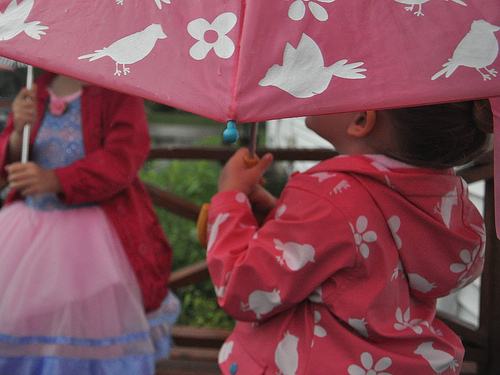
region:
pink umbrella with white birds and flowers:
[5, 5, 491, 127]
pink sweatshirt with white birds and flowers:
[200, 101, 485, 368]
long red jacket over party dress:
[0, 66, 170, 311]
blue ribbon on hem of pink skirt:
[2, 290, 192, 370]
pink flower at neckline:
[36, 76, 81, 112]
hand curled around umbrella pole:
[10, 65, 40, 157]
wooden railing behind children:
[115, 130, 491, 360]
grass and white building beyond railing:
[140, 110, 495, 350]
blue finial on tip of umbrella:
[211, 111, 241, 142]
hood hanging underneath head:
[343, 105, 491, 286]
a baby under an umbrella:
[208, 43, 481, 374]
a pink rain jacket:
[213, 158, 490, 372]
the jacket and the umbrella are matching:
[7, 0, 484, 372]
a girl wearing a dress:
[8, 79, 198, 374]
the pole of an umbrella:
[14, 57, 49, 206]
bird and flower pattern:
[37, 8, 304, 80]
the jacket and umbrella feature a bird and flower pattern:
[0, 1, 497, 368]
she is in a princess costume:
[6, 77, 198, 371]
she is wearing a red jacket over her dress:
[11, 70, 191, 352]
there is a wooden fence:
[11, 145, 498, 372]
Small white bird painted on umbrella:
[76, 20, 168, 77]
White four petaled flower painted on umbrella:
[185, 9, 237, 61]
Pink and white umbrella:
[1, 0, 498, 247]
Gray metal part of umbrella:
[248, 121, 256, 154]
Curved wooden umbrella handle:
[196, 201, 209, 246]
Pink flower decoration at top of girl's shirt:
[47, 97, 66, 114]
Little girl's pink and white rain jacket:
[207, 152, 487, 373]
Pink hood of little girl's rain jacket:
[311, 158, 487, 301]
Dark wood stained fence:
[151, 144, 332, 372]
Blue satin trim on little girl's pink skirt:
[0, 291, 184, 373]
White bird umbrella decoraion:
[73, 22, 179, 78]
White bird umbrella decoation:
[255, 31, 374, 100]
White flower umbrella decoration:
[178, 11, 239, 69]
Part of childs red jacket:
[118, 196, 153, 241]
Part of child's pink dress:
[25, 244, 102, 302]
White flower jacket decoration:
[346, 209, 382, 276]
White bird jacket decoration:
[264, 237, 324, 274]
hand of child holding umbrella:
[213, 147, 272, 194]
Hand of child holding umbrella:
[4, 159, 49, 206]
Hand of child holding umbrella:
[6, 87, 48, 129]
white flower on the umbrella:
[188, 10, 235, 56]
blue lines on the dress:
[0, 328, 172, 373]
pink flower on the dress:
[47, 96, 69, 114]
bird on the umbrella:
[80, 25, 167, 77]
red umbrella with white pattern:
[3, 0, 498, 117]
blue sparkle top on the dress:
[22, 92, 108, 208]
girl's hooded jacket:
[207, 159, 484, 371]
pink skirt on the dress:
[2, 203, 171, 367]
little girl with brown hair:
[316, 96, 491, 170]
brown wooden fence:
[143, 140, 225, 365]